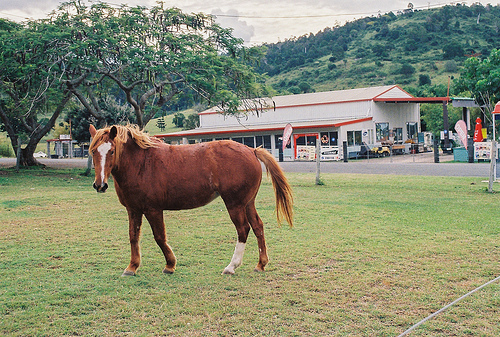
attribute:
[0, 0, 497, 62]
skies — grey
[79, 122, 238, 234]
horse — brown